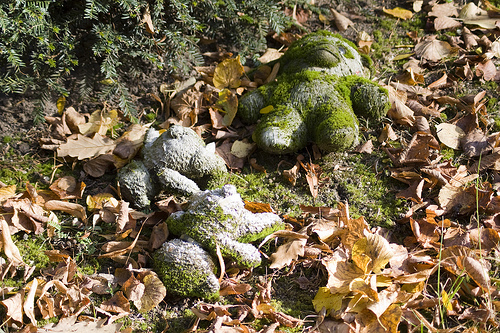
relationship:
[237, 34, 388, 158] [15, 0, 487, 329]
animal in woods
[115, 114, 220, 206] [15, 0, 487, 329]
animal inside woods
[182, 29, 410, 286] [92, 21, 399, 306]
moss on stuffed animals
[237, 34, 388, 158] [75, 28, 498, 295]
animal on ground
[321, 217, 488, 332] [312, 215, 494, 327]
leaves and grass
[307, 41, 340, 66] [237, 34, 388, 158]
mouth of animal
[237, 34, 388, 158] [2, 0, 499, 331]
animal on ground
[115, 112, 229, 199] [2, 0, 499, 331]
animal on ground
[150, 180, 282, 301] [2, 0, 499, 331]
doll on ground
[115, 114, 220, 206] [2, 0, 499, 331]
animal on ground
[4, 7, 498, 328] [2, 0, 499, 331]
leaves on ground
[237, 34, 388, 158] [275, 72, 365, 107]
animal covered in moss